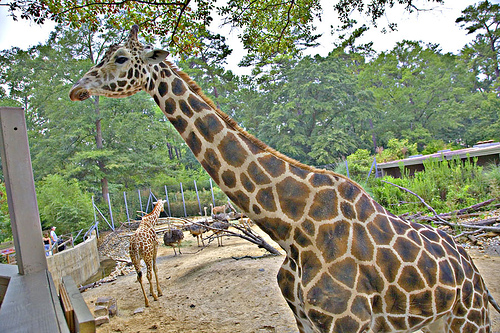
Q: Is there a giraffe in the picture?
A: Yes, there is a giraffe.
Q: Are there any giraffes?
A: Yes, there is a giraffe.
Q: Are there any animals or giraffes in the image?
A: Yes, there is a giraffe.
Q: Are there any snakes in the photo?
A: No, there are no snakes.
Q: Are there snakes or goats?
A: No, there are no snakes or goats.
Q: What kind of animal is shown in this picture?
A: The animal is a giraffe.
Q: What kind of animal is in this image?
A: The animal is a giraffe.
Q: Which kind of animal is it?
A: The animal is a giraffe.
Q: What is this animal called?
A: This is a giraffe.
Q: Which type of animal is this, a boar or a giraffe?
A: This is a giraffe.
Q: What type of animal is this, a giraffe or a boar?
A: This is a giraffe.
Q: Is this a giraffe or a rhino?
A: This is a giraffe.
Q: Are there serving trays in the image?
A: No, there are no serving trays.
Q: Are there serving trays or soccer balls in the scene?
A: No, there are no serving trays or soccer balls.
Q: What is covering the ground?
A: The dirt is covering the ground.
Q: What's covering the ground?
A: The dirt is covering the ground.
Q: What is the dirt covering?
A: The dirt is covering the ground.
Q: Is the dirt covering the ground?
A: Yes, the dirt is covering the ground.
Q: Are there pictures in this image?
A: No, there are no pictures.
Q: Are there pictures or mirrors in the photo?
A: No, there are no pictures or mirrors.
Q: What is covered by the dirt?
A: The ground is covered by the dirt.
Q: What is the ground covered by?
A: The ground is covered by the dirt.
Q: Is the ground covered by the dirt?
A: Yes, the ground is covered by the dirt.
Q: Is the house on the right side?
A: Yes, the house is on the right of the image.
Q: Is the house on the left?
A: No, the house is on the right of the image.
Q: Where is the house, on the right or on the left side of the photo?
A: The house is on the right of the image.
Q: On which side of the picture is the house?
A: The house is on the right of the image.